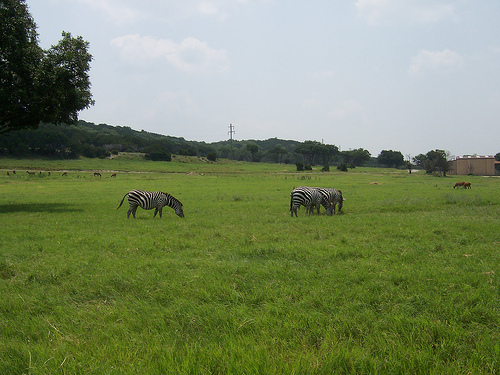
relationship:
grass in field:
[55, 245, 452, 357] [13, 168, 482, 360]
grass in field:
[19, 305, 127, 371] [13, 168, 482, 360]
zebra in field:
[117, 189, 185, 219] [24, 173, 473, 351]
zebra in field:
[289, 186, 334, 218] [13, 168, 482, 360]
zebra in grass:
[117, 189, 185, 219] [55, 280, 411, 357]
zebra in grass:
[284, 184, 321, 220] [44, 244, 484, 351]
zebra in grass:
[323, 189, 343, 215] [0, 271, 483, 371]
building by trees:
[449, 161, 485, 179] [418, 149, 451, 178]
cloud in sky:
[137, 51, 273, 96] [90, 5, 480, 126]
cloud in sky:
[358, 30, 476, 128] [79, 10, 483, 120]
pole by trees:
[222, 114, 248, 177] [201, 137, 291, 165]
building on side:
[448, 154, 496, 175] [444, 37, 498, 273]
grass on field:
[102, 230, 445, 340] [2, 157, 498, 369]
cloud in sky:
[281, 14, 438, 93] [82, 5, 439, 167]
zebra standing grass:
[117, 189, 185, 219] [64, 240, 439, 354]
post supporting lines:
[224, 120, 237, 140] [180, 112, 356, 144]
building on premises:
[448, 154, 496, 175] [386, 172, 483, 242]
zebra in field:
[109, 178, 179, 224] [27, 222, 471, 352]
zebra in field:
[280, 175, 364, 215] [27, 222, 471, 352]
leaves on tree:
[39, 77, 60, 92] [4, 8, 94, 136]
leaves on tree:
[15, 64, 35, 74] [0, 20, 99, 141]